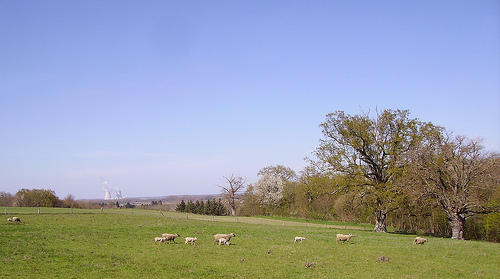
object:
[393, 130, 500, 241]
tree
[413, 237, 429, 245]
sheep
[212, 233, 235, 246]
animals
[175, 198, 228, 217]
trees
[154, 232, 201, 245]
animals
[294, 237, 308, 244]
sheep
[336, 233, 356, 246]
sheep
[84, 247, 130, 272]
grass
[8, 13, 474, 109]
sky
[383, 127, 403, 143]
leaves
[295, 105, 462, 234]
tree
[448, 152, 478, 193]
branches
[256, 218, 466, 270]
pasture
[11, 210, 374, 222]
posts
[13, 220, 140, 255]
field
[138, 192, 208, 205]
distance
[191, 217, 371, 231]
pathway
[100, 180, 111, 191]
smoke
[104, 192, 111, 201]
building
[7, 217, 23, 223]
sheep